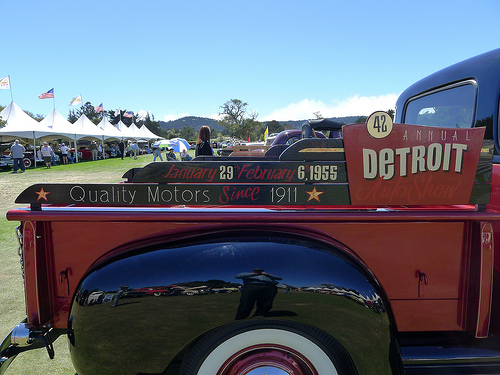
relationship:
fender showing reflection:
[67, 225, 402, 374] [228, 267, 283, 320]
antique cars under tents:
[1, 142, 136, 168] [1, 101, 164, 141]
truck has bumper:
[0, 48, 499, 375] [0, 314, 66, 375]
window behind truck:
[400, 76, 479, 127] [0, 48, 499, 375]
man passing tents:
[40, 140, 55, 169] [1, 101, 164, 141]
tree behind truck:
[219, 96, 259, 140] [0, 48, 499, 375]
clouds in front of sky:
[261, 92, 397, 121] [4, 2, 484, 121]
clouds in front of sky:
[135, 107, 225, 123] [4, 2, 484, 121]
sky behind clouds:
[4, 2, 484, 121] [261, 92, 397, 121]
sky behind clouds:
[4, 2, 484, 121] [135, 107, 225, 123]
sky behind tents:
[4, 2, 484, 121] [1, 101, 164, 141]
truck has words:
[0, 48, 499, 375] [68, 161, 338, 204]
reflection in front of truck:
[228, 267, 283, 320] [0, 48, 499, 375]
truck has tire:
[0, 48, 499, 375] [176, 317, 357, 374]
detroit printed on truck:
[361, 142, 467, 180] [0, 48, 499, 375]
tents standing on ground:
[1, 101, 164, 141] [0, 148, 217, 374]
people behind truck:
[10, 125, 213, 174] [0, 48, 499, 375]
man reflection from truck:
[233, 267, 281, 320] [0, 48, 499, 375]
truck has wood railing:
[0, 48, 499, 375] [14, 138, 493, 203]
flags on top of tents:
[1, 76, 147, 125] [1, 101, 164, 141]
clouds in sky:
[261, 92, 397, 121] [4, 2, 484, 121]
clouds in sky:
[135, 107, 225, 123] [4, 2, 484, 121]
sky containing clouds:
[4, 2, 484, 121] [261, 92, 397, 121]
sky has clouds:
[4, 2, 484, 121] [261, 92, 397, 121]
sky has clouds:
[4, 2, 484, 121] [135, 107, 225, 123]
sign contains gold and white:
[342, 110, 486, 201] [362, 109, 471, 181]